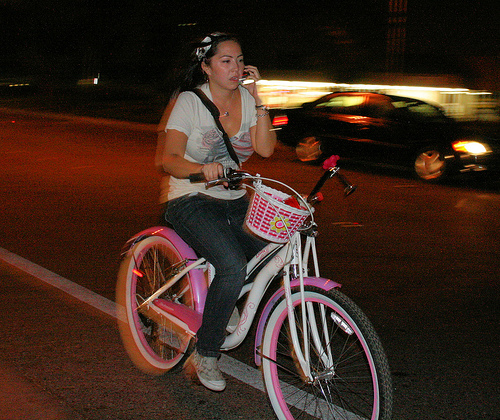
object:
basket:
[246, 183, 317, 244]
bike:
[113, 154, 395, 419]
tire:
[260, 285, 396, 420]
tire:
[115, 236, 190, 379]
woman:
[157, 33, 277, 394]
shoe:
[192, 351, 228, 393]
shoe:
[225, 307, 240, 334]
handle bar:
[188, 167, 234, 184]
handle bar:
[321, 166, 359, 196]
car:
[262, 90, 500, 194]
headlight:
[451, 140, 493, 157]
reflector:
[328, 309, 353, 336]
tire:
[294, 134, 326, 164]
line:
[0, 238, 395, 419]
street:
[0, 105, 497, 419]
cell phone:
[242, 65, 249, 82]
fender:
[254, 275, 344, 369]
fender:
[118, 225, 206, 318]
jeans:
[161, 190, 271, 359]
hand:
[201, 162, 229, 187]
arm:
[160, 90, 203, 177]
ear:
[201, 59, 211, 77]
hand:
[240, 65, 264, 97]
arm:
[248, 101, 275, 159]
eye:
[220, 58, 232, 64]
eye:
[238, 58, 246, 64]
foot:
[191, 349, 228, 393]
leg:
[173, 212, 248, 355]